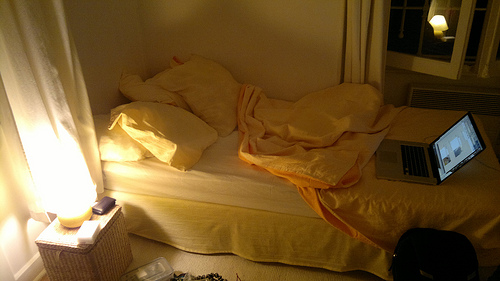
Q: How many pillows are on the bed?
A: 4.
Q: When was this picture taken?
A: Night time.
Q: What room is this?
A: Bedroom.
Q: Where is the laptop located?
A: Top of bed.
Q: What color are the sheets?
A: White.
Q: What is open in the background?
A: Window.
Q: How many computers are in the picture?
A: 1.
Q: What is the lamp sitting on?
A: Basket.